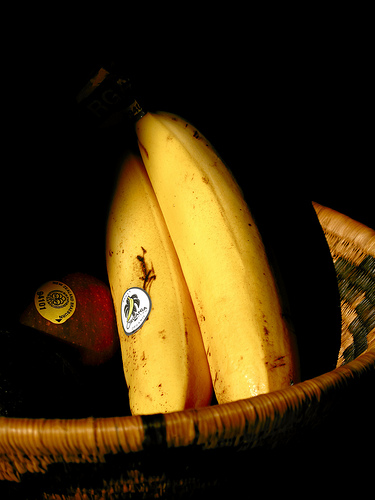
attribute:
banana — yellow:
[124, 104, 293, 399]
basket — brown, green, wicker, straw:
[15, 187, 372, 498]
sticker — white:
[118, 286, 150, 332]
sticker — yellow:
[33, 280, 74, 325]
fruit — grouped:
[25, 72, 291, 394]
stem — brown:
[86, 67, 153, 121]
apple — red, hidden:
[19, 272, 111, 370]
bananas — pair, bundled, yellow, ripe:
[95, 89, 301, 404]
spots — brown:
[135, 245, 160, 300]